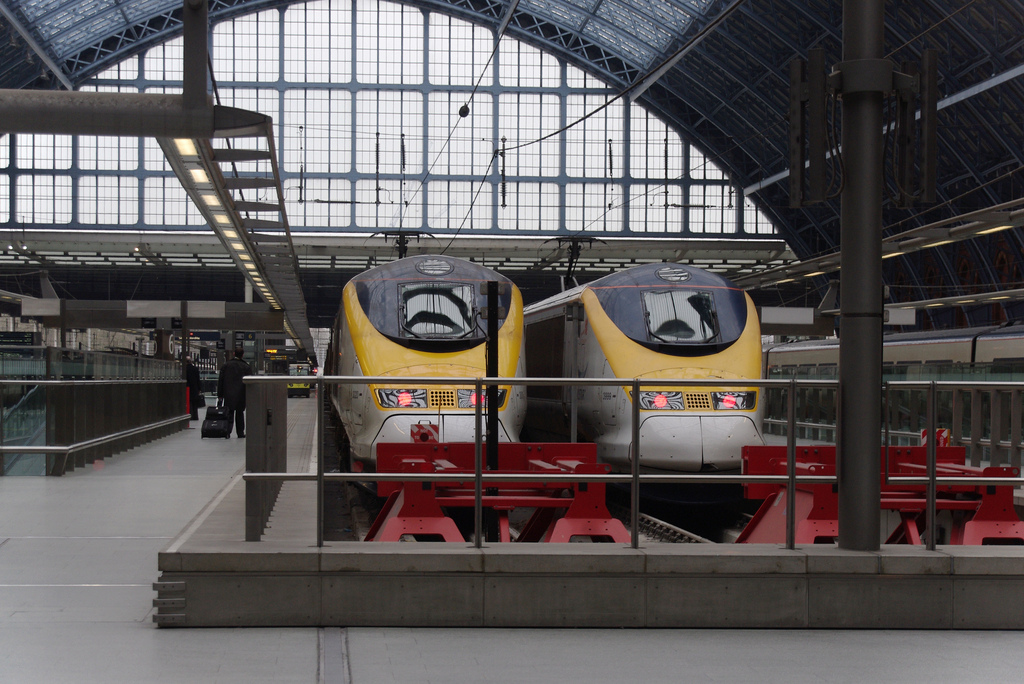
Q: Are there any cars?
A: No, there are no cars.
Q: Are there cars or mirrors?
A: No, there are no cars or mirrors.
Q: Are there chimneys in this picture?
A: No, there are no chimneys.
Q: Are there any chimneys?
A: No, there are no chimneys.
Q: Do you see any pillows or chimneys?
A: No, there are no chimneys or pillows.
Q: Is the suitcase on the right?
A: No, the suitcase is on the left of the image.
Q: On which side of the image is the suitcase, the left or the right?
A: The suitcase is on the left of the image.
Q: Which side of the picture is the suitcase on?
A: The suitcase is on the left of the image.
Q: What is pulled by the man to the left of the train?
A: The suitcase is pulled by the man.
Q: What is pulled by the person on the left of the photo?
A: The suitcase is pulled by the man.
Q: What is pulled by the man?
A: The suitcase is pulled by the man.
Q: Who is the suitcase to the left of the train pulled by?
A: The suitcase is pulled by the man.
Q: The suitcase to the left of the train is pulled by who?
A: The suitcase is pulled by the man.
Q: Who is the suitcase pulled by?
A: The suitcase is pulled by the man.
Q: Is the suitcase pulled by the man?
A: Yes, the suitcase is pulled by the man.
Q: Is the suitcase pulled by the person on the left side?
A: Yes, the suitcase is pulled by the man.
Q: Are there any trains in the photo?
A: Yes, there is a train.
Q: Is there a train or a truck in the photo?
A: Yes, there is a train.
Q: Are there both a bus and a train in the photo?
A: No, there is a train but no buses.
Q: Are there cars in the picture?
A: No, there are no cars.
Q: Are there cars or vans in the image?
A: No, there are no cars or vans.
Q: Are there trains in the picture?
A: Yes, there is a train.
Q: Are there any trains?
A: Yes, there is a train.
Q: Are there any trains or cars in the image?
A: Yes, there is a train.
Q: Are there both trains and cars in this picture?
A: No, there is a train but no cars.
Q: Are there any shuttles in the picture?
A: No, there are no shuttles.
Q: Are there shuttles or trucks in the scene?
A: No, there are no shuttles or trucks.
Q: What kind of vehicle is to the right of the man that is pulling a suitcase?
A: The vehicle is a train.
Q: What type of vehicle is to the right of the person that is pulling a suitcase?
A: The vehicle is a train.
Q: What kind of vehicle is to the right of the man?
A: The vehicle is a train.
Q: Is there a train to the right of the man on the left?
A: Yes, there is a train to the right of the man.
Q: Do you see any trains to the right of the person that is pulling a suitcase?
A: Yes, there is a train to the right of the man.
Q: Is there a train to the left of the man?
A: No, the train is to the right of the man.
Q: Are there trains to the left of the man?
A: No, the train is to the right of the man.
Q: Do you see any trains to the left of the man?
A: No, the train is to the right of the man.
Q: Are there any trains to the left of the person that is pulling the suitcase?
A: No, the train is to the right of the man.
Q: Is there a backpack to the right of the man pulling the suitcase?
A: No, there is a train to the right of the man.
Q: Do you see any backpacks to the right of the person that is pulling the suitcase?
A: No, there is a train to the right of the man.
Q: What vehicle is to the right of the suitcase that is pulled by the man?
A: The vehicle is a train.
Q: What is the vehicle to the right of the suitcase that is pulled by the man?
A: The vehicle is a train.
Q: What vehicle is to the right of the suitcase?
A: The vehicle is a train.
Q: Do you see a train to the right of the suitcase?
A: Yes, there is a train to the right of the suitcase.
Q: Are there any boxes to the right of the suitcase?
A: No, there is a train to the right of the suitcase.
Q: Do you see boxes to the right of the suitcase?
A: No, there is a train to the right of the suitcase.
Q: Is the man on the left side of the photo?
A: Yes, the man is on the left of the image.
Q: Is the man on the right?
A: No, the man is on the left of the image.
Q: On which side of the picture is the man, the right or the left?
A: The man is on the left of the image.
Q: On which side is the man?
A: The man is on the left of the image.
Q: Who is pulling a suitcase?
A: The man is pulling a suitcase.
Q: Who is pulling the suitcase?
A: The man is pulling a suitcase.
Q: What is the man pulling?
A: The man is pulling a suitcase.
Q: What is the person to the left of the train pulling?
A: The man is pulling a suitcase.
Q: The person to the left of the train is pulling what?
A: The man is pulling a suitcase.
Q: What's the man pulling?
A: The man is pulling a suitcase.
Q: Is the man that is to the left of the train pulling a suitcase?
A: Yes, the man is pulling a suitcase.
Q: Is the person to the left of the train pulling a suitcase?
A: Yes, the man is pulling a suitcase.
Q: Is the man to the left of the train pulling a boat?
A: No, the man is pulling a suitcase.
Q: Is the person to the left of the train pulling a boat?
A: No, the man is pulling a suitcase.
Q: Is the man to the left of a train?
A: Yes, the man is to the left of a train.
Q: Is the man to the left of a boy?
A: No, the man is to the left of a train.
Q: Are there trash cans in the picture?
A: No, there are no trash cans.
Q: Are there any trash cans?
A: No, there are no trash cans.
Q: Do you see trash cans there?
A: No, there are no trash cans.